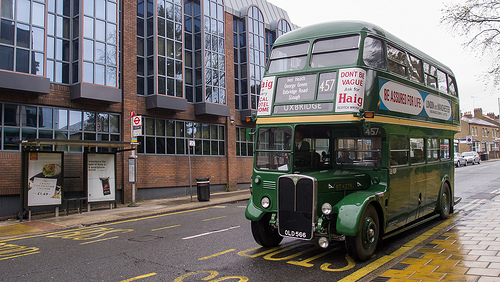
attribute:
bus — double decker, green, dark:
[244, 20, 463, 263]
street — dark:
[1, 160, 499, 282]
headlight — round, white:
[321, 202, 331, 216]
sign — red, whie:
[130, 113, 143, 138]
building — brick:
[0, 0, 304, 214]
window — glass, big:
[81, 60, 94, 82]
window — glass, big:
[93, 61, 106, 86]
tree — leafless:
[437, 0, 499, 88]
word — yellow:
[237, 240, 377, 272]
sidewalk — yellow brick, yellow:
[371, 193, 499, 281]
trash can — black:
[195, 176, 212, 202]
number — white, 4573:
[318, 79, 336, 92]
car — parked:
[463, 150, 481, 164]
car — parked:
[453, 152, 468, 168]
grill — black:
[277, 174, 316, 239]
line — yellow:
[200, 246, 235, 260]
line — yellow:
[153, 223, 181, 232]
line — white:
[182, 223, 242, 240]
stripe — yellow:
[255, 111, 462, 133]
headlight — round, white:
[261, 197, 269, 207]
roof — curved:
[271, 20, 456, 78]